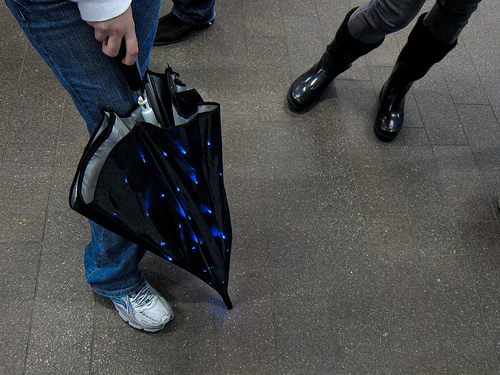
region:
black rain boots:
[287, 8, 452, 140]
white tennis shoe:
[97, 284, 172, 331]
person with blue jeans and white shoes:
[13, 3, 173, 332]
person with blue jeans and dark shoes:
[152, 1, 216, 43]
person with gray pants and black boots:
[287, 0, 480, 145]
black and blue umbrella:
[65, 33, 235, 308]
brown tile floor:
[2, 7, 499, 372]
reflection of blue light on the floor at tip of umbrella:
[215, 297, 232, 315]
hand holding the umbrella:
[85, 5, 138, 65]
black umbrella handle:
[113, 31, 144, 90]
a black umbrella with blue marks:
[93, 58, 248, 322]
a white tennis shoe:
[101, 278, 183, 338]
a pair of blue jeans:
[7, 2, 168, 290]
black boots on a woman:
[282, 6, 404, 114]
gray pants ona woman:
[326, 0, 486, 58]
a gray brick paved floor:
[1, 2, 496, 371]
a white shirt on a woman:
[76, 3, 150, 17]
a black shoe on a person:
[141, 9, 239, 50]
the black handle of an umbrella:
[103, 32, 144, 89]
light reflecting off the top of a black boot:
[277, 65, 335, 103]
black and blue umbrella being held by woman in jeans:
[82, 61, 284, 306]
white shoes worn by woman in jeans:
[87, 263, 187, 333]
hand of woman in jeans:
[82, 11, 157, 68]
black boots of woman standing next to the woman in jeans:
[294, 17, 448, 142]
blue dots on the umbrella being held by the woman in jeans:
[136, 156, 206, 211]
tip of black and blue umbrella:
[208, 276, 247, 314]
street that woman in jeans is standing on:
[270, 168, 482, 342]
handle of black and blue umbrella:
[105, 49, 163, 119]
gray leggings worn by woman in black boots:
[344, 0, 476, 60]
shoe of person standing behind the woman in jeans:
[154, 8, 231, 51]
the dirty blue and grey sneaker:
[108, 278, 170, 328]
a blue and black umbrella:
[62, 27, 234, 307]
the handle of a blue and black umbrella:
[112, 32, 148, 101]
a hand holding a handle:
[87, 12, 137, 63]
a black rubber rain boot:
[292, 11, 382, 116]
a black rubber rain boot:
[370, 13, 457, 144]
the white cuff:
[80, 2, 131, 20]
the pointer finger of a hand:
[122, 13, 140, 65]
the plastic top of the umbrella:
[221, 290, 236, 315]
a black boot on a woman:
[285, 16, 380, 112]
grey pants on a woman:
[340, 0, 486, 41]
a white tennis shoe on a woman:
[95, 286, 180, 339]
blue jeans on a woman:
[7, 5, 157, 288]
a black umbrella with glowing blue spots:
[72, 55, 257, 315]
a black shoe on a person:
[150, 16, 216, 41]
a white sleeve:
[73, 1, 145, 23]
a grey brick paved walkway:
[1, 2, 496, 364]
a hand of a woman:
[89, 8, 155, 67]